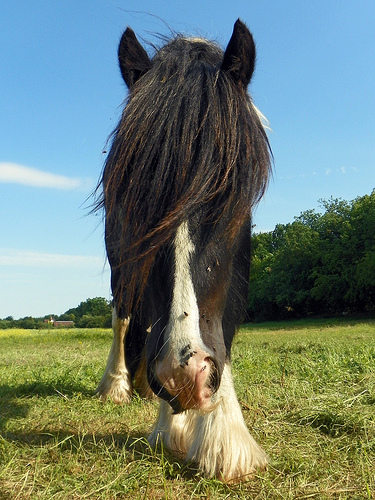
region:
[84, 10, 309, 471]
this is a horse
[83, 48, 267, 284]
the mane of a horse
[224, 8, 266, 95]
the ear of a horse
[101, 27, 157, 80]
the ear of a horse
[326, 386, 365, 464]
this is grass on the ground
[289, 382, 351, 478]
this is grass on the ground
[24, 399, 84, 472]
this is grass on the ground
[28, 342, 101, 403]
this is grass on the ground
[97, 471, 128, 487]
this is grass on the ground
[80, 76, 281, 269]
the bangs of a horse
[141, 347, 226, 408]
the nose of a horse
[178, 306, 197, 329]
a fly on a horses nose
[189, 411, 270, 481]
a hairy hoof of a hose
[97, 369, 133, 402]
a hairy hoof of a hose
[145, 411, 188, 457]
a hairy hoof of a hose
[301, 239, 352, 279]
the leaves of a tree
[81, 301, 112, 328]
the leaves of a horse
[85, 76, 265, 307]
The horses mane is long.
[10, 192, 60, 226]
The sky is blue.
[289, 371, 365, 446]
The grass is green.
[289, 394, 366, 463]
The grass in the forefront is long.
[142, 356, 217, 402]
The horese nose is pink.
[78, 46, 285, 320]
The horses mane brown.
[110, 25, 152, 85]
The horses right ear is brown.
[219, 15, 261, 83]
The horses left ear is brown.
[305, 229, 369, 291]
The tree leaves are green.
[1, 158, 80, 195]
The cloud is white.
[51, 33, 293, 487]
The horse is in a big field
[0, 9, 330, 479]
The horse is casting a shadow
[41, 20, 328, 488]
The horse has very long hair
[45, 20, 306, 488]
The horse is eating the grass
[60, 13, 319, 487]
A horse is standing in some grass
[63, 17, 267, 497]
A horse is out in the sunshine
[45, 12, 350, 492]
The horse is owned by a rancher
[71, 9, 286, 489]
The horse is looking for food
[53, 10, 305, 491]
The horse is close to some trees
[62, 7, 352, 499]
The horse is enjoying the day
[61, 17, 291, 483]
a large full grown Clydesdale horse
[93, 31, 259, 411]
the head of a Clydesdale horse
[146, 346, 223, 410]
the nose of a Clydesdale horse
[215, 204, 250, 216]
the eye of a Clydesdale horse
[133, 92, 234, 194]
the mane of a Clydesdale horse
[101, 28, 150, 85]
the right ear of a Clydesdale horse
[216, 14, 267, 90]
the left ear of a Clydesdale horse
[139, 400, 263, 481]
the front leg of a Clydesdale horse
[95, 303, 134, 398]
the hind leg of a Clydesdale horse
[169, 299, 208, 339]
a fly on the face of a horse